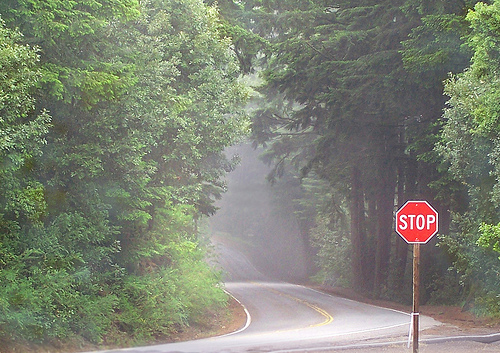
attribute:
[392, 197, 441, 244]
sign — red, white, stop, octagon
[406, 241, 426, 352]
pole — brown, wooden, wood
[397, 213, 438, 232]
letters — white, stop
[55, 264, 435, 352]
road — gray, paved, windy, empty, lined, fog, leading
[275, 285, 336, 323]
stripe — yellow, painted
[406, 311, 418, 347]
ribbon — white, tied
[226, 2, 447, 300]
tree — pine, tall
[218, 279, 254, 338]
line — white, painted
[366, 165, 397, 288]
trunk — brown